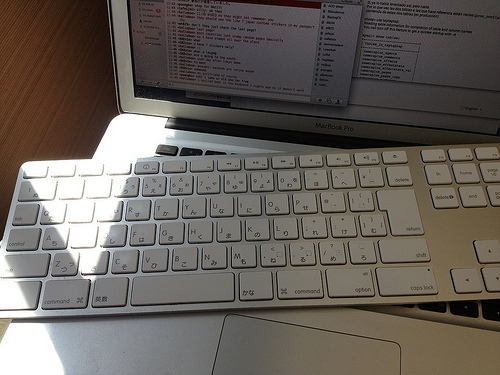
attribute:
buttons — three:
[450, 230, 498, 298]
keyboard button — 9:
[425, 163, 452, 185]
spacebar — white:
[130, 266, 238, 306]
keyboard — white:
[18, 153, 500, 300]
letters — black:
[145, 189, 332, 250]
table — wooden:
[0, 1, 122, 238]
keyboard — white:
[1, 138, 494, 322]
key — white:
[109, 246, 137, 275]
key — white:
[258, 241, 285, 265]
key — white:
[123, 200, 148, 220]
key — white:
[347, 238, 374, 263]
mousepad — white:
[204, 309, 411, 373]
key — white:
[244, 218, 271, 242]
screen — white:
[197, 24, 476, 124]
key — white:
[205, 196, 238, 218]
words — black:
[175, 0, 495, 92]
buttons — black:
[92, 123, 233, 193]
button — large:
[372, 186, 427, 236]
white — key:
[127, 199, 155, 217]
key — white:
[95, 199, 123, 222]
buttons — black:
[419, 304, 497, 321]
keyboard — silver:
[13, 130, 455, 300]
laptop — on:
[2, 1, 496, 371]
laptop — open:
[21, 13, 447, 347]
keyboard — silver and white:
[12, 95, 459, 326]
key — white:
[152, 196, 181, 226]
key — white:
[105, 248, 137, 276]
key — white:
[52, 182, 94, 226]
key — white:
[63, 190, 102, 227]